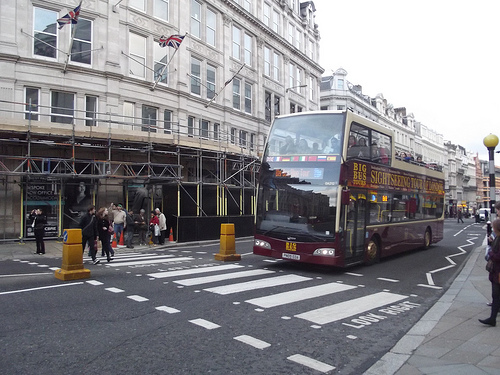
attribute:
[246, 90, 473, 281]
bus — maroon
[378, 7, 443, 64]
sky — overcast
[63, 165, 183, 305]
people — gathered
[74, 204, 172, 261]
people — grouped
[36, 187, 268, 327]
dividers — yellow , concrete 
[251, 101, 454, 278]
bus — double decker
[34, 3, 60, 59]
window — rectangular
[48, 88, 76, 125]
window — rectangular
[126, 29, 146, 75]
window — rectangular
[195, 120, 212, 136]
window — rectangular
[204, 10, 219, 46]
window — rectangular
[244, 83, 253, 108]
window — rectangular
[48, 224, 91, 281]
pillar — yellow, concrete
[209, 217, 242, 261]
pillar — yellow, concrete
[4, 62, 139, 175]
window — rectangular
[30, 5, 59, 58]
window — rectangular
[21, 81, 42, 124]
window — rectangular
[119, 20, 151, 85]
window — rectangular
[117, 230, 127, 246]
cone — orange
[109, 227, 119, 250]
cone — orange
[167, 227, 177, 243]
cone — orange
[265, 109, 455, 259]
bus — double decker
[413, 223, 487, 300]
zigzag — white , line 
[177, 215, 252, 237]
wall — black 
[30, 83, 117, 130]
window — rectangular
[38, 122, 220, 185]
awning — metal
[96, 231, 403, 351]
lines — white